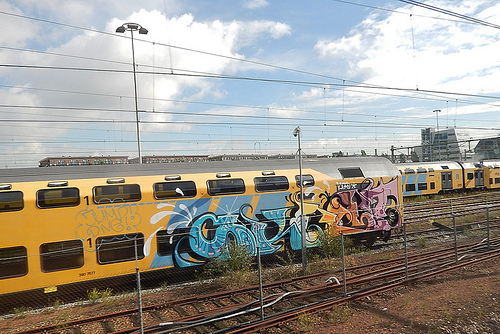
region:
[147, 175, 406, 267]
The graffiti on the side of the train.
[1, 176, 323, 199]
The top level of windows of the graffiti train.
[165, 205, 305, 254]
The blue graffiti word on the train.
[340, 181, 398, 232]
The pink graffiti letters on the train.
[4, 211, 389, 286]
The lower level windows on the graffiti train.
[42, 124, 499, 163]
The buildings in the distance.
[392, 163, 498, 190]
The other train near the right.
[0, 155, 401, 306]
a yellow train passenger car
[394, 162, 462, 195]
a yellow train passenger car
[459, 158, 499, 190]
a yellow train passenger car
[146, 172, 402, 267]
spray painted grafitti on train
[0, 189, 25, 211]
an upper train passenger window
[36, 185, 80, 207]
an upper train passenger window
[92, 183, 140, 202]
an upper train passenger window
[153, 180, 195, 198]
an upper train passenger window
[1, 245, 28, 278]
a lower train passenger window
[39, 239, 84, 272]
a lower train passenger window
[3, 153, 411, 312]
train car with graffiti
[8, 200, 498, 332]
chain link fence around rail yard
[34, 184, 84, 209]
rectangle window in train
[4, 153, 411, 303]
yellow train with silver roof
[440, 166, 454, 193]
doors to enter and exit train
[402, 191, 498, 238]
train tracks over grown with grass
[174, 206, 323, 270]
blue graffiti on train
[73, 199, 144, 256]
gray graffiti on train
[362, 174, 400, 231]
pink graffiti on train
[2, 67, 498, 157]
blue sky with white cloud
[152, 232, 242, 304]
tall clear link fence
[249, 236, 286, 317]
silver post on clear link fence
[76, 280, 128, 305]
green bush at side of track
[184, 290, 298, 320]
long silver electrical wire on track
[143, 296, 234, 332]
lines running across track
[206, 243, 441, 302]
long section of brown train tracks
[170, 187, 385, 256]
graffiti on side of train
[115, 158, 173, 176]
silver top on train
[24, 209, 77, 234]
yellow paint on side of train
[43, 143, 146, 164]
top of brown apartment building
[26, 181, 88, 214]
long window on train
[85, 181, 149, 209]
long window on train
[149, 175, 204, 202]
long window on train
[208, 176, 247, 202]
long window on train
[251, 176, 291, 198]
long window on train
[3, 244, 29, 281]
long window on train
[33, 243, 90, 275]
long window on train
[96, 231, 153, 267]
long window on train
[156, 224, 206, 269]
long window on train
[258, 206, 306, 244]
long window on train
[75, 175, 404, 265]
graffiti on the side of a train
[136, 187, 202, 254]
splashing water on the side of a train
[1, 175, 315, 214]
windows on the upper level of a train